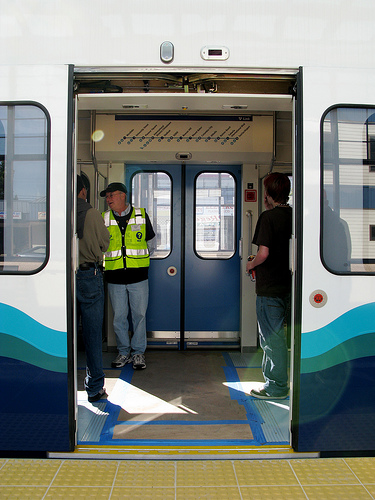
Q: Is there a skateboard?
A: No, there are no skateboards.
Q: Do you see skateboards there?
A: No, there are no skateboards.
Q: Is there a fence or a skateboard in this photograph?
A: No, there are no skateboards or fences.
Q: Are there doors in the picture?
A: Yes, there is a door.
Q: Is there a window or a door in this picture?
A: Yes, there is a door.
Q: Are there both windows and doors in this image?
A: Yes, there are both a door and a window.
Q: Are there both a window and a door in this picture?
A: Yes, there are both a door and a window.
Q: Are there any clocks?
A: No, there are no clocks.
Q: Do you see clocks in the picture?
A: No, there are no clocks.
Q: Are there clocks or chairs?
A: No, there are no clocks or chairs.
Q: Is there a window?
A: Yes, there is a window.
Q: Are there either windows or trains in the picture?
A: Yes, there is a window.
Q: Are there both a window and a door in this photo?
A: Yes, there are both a window and a door.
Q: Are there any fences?
A: No, there are no fences.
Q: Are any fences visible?
A: No, there are no fences.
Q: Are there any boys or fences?
A: No, there are no fences or boys.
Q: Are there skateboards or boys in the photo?
A: No, there are no boys or skateboards.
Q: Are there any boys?
A: No, there are no boys.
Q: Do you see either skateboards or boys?
A: No, there are no boys or skateboards.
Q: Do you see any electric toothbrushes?
A: No, there are no electric toothbrushes.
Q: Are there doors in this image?
A: Yes, there is a door.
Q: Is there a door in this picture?
A: Yes, there is a door.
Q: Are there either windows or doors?
A: Yes, there is a door.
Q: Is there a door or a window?
A: Yes, there is a door.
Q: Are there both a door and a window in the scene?
A: Yes, there are both a door and a window.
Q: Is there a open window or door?
A: Yes, there is an open door.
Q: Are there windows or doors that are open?
A: Yes, the door is open.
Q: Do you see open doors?
A: Yes, there is an open door.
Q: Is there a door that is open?
A: Yes, there is a door that is open.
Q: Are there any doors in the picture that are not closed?
A: Yes, there is a open door.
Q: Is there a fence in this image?
A: No, there are no fences.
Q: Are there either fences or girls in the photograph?
A: No, there are no fences or girls.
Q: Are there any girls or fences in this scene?
A: No, there are no fences or girls.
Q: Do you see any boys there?
A: No, there are no boys.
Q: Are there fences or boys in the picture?
A: No, there are no boys or fences.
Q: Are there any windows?
A: Yes, there is a window.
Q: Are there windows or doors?
A: Yes, there is a window.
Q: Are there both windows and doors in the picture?
A: Yes, there are both a window and a door.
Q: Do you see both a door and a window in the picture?
A: Yes, there are both a window and a door.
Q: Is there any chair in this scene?
A: No, there are no chairs.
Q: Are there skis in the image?
A: No, there are no skis.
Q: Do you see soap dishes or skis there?
A: No, there are no skis or soap dishes.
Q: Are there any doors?
A: Yes, there is a door.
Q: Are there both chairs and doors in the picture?
A: No, there is a door but no chairs.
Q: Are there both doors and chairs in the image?
A: No, there is a door but no chairs.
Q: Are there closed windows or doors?
A: Yes, there is a closed door.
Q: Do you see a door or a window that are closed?
A: Yes, the door is closed.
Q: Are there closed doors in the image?
A: Yes, there is a closed door.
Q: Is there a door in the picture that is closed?
A: Yes, there is a door that is closed.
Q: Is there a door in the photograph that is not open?
A: Yes, there is an closed door.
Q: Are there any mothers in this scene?
A: No, there are no mothers.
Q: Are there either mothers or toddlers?
A: No, there are no mothers or toddlers.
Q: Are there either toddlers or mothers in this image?
A: No, there are no mothers or toddlers.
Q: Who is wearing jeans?
A: The man is wearing jeans.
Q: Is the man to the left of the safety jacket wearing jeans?
A: Yes, the man is wearing jeans.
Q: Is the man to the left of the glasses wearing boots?
A: No, the man is wearing jeans.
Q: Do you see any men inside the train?
A: Yes, there is a man inside the train.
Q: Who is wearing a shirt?
A: The man is wearing a shirt.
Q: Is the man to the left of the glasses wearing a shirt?
A: Yes, the man is wearing a shirt.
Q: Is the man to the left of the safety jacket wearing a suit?
A: No, the man is wearing a shirt.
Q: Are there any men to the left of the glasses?
A: Yes, there is a man to the left of the glasses.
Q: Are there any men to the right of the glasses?
A: No, the man is to the left of the glasses.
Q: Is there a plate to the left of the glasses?
A: No, there is a man to the left of the glasses.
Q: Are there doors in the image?
A: Yes, there is a door.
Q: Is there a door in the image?
A: Yes, there is a door.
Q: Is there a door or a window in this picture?
A: Yes, there is a door.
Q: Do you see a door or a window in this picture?
A: Yes, there is a door.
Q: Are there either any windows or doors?
A: Yes, there is a door.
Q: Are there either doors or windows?
A: Yes, there is a door.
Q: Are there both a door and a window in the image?
A: Yes, there are both a door and a window.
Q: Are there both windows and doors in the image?
A: Yes, there are both a door and a window.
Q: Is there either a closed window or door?
A: Yes, there is a closed door.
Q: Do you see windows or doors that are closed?
A: Yes, the door is closed.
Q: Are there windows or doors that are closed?
A: Yes, the door is closed.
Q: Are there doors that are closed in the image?
A: Yes, there is a closed door.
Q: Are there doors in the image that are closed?
A: Yes, there is a door that is closed.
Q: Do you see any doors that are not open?
A: Yes, there is an closed door.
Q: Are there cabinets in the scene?
A: No, there are no cabinets.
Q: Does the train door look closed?
A: Yes, the door is closed.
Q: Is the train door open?
A: No, the door is closed.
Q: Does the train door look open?
A: No, the door is closed.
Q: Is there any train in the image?
A: Yes, there is a train.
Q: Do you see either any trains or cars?
A: Yes, there is a train.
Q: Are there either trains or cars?
A: Yes, there is a train.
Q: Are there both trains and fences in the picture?
A: No, there is a train but no fences.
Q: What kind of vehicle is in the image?
A: The vehicle is a train.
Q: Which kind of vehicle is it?
A: The vehicle is a train.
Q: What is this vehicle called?
A: This is a train.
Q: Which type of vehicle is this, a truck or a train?
A: This is a train.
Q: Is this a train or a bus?
A: This is a train.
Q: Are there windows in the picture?
A: Yes, there is a window.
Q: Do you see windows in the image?
A: Yes, there is a window.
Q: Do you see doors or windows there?
A: Yes, there is a window.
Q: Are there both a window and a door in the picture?
A: Yes, there are both a window and a door.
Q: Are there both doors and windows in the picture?
A: Yes, there are both a window and a door.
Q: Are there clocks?
A: No, there are no clocks.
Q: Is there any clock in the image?
A: No, there are no clocks.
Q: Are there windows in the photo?
A: Yes, there is a window.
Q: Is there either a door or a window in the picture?
A: Yes, there is a window.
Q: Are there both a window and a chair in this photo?
A: No, there is a window but no chairs.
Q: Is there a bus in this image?
A: No, there are no buses.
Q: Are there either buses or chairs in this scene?
A: No, there are no buses or chairs.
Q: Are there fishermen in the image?
A: No, there are no fishermen.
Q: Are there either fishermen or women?
A: No, there are no fishermen or women.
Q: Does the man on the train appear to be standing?
A: Yes, the man is standing.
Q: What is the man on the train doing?
A: The man is standing.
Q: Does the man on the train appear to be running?
A: No, the man is standing.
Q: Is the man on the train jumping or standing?
A: The man is standing.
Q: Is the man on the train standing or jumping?
A: The man is standing.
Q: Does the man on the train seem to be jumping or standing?
A: The man is standing.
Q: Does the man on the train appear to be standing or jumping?
A: The man is standing.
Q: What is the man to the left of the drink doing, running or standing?
A: The man is standing.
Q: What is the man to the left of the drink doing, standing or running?
A: The man is standing.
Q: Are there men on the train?
A: Yes, there is a man on the train.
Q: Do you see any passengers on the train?
A: No, there is a man on the train.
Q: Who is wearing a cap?
A: The man is wearing a cap.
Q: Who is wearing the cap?
A: The man is wearing a cap.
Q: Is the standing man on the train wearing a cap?
A: Yes, the man is wearing a cap.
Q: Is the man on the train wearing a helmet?
A: No, the man is wearing a cap.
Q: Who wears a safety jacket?
A: The man wears a safety jacket.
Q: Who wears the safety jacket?
A: The man wears a safety jacket.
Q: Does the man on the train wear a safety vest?
A: Yes, the man wears a safety vest.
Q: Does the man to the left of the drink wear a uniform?
A: No, the man wears a safety vest.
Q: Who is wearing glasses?
A: The man is wearing glasses.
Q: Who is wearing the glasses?
A: The man is wearing glasses.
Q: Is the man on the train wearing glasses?
A: Yes, the man is wearing glasses.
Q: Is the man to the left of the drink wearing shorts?
A: No, the man is wearing glasses.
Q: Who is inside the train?
A: The man is inside the train.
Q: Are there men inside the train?
A: Yes, there is a man inside the train.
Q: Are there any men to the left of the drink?
A: Yes, there is a man to the left of the drink.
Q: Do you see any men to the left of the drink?
A: Yes, there is a man to the left of the drink.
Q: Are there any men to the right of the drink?
A: No, the man is to the left of the drink.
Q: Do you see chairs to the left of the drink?
A: No, there is a man to the left of the drink.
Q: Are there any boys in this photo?
A: No, there are no boys.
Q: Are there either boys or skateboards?
A: No, there are no boys or skateboards.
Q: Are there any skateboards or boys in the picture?
A: No, there are no boys or skateboards.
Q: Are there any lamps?
A: No, there are no lamps.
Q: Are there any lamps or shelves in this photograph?
A: No, there are no lamps or shelves.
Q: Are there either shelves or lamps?
A: No, there are no lamps or shelves.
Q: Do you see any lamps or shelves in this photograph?
A: No, there are no lamps or shelves.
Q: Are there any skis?
A: No, there are no skis.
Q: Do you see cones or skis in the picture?
A: No, there are no skis or cones.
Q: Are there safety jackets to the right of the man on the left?
A: Yes, there is a safety jacket to the right of the man.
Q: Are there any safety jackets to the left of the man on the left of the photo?
A: No, the safety jacket is to the right of the man.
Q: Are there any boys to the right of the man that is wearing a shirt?
A: No, there is a safety jacket to the right of the man.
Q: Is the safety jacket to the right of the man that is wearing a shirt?
A: Yes, the safety jacket is to the right of the man.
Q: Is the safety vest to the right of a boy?
A: No, the safety vest is to the right of the man.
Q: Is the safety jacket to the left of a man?
A: No, the safety jacket is to the right of a man.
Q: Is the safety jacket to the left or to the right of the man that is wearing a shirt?
A: The safety jacket is to the right of the man.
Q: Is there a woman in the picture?
A: No, there are no women.